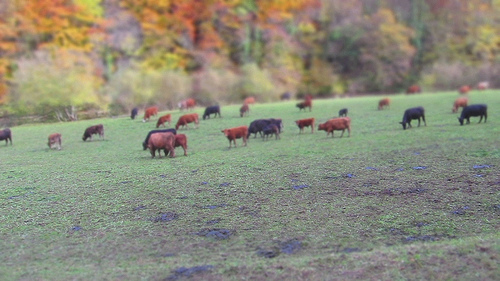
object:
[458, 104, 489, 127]
cow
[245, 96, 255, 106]
cow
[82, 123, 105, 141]
cow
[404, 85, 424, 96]
cow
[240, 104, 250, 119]
cow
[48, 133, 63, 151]
cow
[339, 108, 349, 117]
cow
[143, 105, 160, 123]
cow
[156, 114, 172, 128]
cow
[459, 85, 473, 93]
cows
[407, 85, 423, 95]
cows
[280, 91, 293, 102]
cows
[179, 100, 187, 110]
cows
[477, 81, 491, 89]
cows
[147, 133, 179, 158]
cow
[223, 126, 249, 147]
cow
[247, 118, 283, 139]
cow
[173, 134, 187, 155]
cow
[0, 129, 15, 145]
cow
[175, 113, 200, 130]
cow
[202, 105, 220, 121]
cow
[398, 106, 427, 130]
cow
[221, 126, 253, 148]
cow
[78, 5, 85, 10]
leaf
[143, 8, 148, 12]
leaf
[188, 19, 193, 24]
leaf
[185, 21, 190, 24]
leaf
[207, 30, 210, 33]
leaf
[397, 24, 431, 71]
leaves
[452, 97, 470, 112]
cows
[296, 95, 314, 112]
cows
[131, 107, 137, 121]
cows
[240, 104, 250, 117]
cows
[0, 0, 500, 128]
tree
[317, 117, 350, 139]
calf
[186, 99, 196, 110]
cows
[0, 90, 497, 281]
field